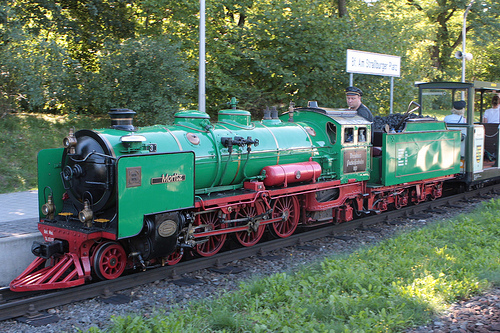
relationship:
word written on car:
[159, 167, 184, 184] [8, 80, 500, 291]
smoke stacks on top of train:
[100, 101, 152, 136] [24, 46, 498, 296]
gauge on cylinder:
[290, 170, 302, 181] [257, 159, 325, 187]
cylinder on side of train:
[257, 159, 325, 187] [37, 96, 498, 198]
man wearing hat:
[340, 82, 375, 140] [344, 85, 364, 95]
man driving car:
[340, 82, 375, 140] [8, 80, 500, 291]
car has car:
[8, 80, 500, 291] [412, 79, 498, 191]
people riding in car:
[484, 94, 499, 123] [412, 79, 498, 191]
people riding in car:
[444, 99, 467, 123] [412, 79, 498, 191]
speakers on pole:
[454, 49, 472, 61] [460, 10, 466, 121]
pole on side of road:
[460, 10, 466, 121] [0, 183, 40, 292]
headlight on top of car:
[61, 133, 81, 150] [8, 80, 500, 291]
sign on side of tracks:
[321, 7, 441, 154] [2, 182, 491, 316]